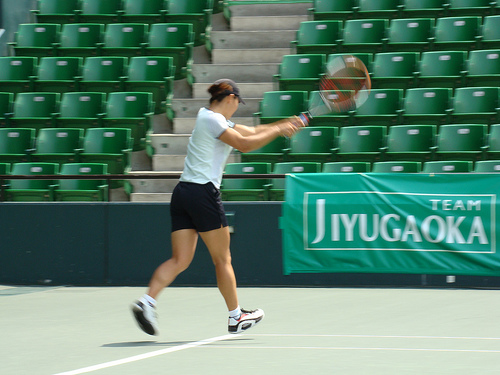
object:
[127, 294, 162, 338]
shoes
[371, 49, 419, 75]
seats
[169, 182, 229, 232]
pants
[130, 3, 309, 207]
stairs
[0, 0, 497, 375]
stadium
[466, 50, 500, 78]
seats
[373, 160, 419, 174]
seats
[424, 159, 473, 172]
seats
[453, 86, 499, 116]
seats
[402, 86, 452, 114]
seats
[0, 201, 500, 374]
court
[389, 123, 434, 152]
chair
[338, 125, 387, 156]
chair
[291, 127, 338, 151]
chair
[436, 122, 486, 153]
chair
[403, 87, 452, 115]
chair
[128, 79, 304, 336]
player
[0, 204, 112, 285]
padding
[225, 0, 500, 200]
green seats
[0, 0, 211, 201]
green seats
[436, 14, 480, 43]
seats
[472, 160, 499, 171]
seats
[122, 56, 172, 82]
seats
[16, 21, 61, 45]
seats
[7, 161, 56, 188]
seats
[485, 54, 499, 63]
white lettering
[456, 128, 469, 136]
white lettering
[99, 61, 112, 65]
white lettering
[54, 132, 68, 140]
white lettering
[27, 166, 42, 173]
white lettering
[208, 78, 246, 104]
cap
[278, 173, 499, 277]
banner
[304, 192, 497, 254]
sign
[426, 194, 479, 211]
text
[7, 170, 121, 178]
railing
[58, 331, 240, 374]
lines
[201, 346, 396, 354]
lines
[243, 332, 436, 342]
lines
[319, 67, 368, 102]
racket net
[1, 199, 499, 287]
wall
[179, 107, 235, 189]
blouse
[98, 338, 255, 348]
shadow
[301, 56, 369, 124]
racket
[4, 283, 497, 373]
tennis court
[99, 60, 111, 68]
tag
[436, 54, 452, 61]
tag